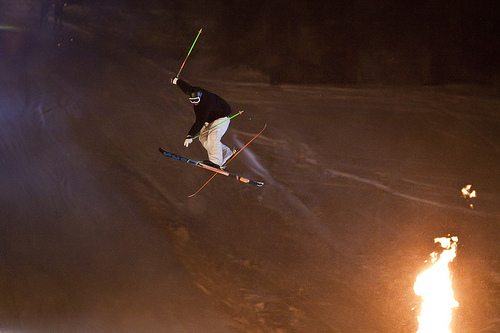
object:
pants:
[197, 112, 234, 169]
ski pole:
[185, 107, 248, 146]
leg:
[197, 118, 235, 162]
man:
[166, 74, 235, 171]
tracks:
[85, 171, 195, 294]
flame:
[406, 231, 463, 332]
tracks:
[326, 164, 492, 221]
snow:
[0, 0, 498, 332]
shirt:
[174, 79, 235, 138]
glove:
[171, 78, 176, 86]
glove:
[180, 137, 192, 147]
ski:
[157, 146, 266, 188]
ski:
[185, 121, 272, 199]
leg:
[197, 117, 229, 168]